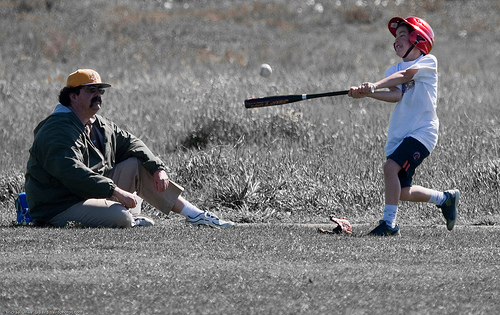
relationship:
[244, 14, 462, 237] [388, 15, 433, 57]
boy with a batting helmet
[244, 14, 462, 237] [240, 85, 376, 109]
boy swinging bat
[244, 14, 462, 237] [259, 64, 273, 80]
boy hitting baseball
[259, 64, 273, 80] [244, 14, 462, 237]
baseball by boy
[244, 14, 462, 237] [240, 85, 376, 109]
boy has a bat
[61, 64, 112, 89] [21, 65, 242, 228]
hat on man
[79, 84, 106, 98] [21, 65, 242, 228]
sunglasses on man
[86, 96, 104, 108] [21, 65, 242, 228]
mustache on man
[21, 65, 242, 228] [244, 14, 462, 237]
man watching boy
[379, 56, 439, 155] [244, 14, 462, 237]
shirt on boy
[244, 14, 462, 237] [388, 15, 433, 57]
boy wearing batting helmet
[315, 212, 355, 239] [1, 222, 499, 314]
glove on grass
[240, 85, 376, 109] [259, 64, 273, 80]
bat hitting baseball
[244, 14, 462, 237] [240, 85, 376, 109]
boy holding bat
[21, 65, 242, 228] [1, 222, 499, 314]
man on grass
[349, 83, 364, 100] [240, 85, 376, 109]
hand on bat